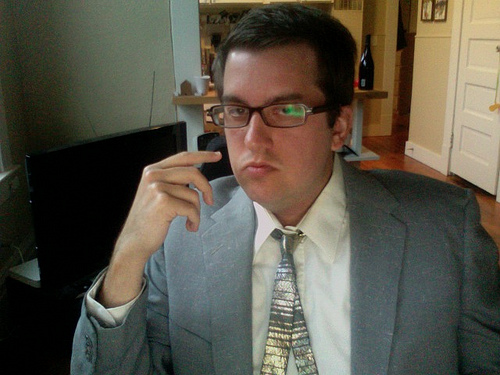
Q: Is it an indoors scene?
A: Yes, it is indoors.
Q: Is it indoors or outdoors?
A: It is indoors.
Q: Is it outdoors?
A: No, it is indoors.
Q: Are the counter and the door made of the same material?
A: Yes, both the counter and the door are made of wood.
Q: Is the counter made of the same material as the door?
A: Yes, both the counter and the door are made of wood.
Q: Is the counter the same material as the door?
A: Yes, both the counter and the door are made of wood.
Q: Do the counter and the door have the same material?
A: Yes, both the counter and the door are made of wood.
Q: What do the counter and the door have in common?
A: The material, both the counter and the door are wooden.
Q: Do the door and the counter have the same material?
A: Yes, both the door and the counter are made of wood.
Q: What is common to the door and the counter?
A: The material, both the door and the counter are wooden.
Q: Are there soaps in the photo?
A: No, there are no soaps.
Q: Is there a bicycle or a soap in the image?
A: No, there are no soaps or bicycles.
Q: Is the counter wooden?
A: Yes, the counter is wooden.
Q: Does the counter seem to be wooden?
A: Yes, the counter is wooden.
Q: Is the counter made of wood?
A: Yes, the counter is made of wood.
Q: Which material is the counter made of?
A: The counter is made of wood.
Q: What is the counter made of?
A: The counter is made of wood.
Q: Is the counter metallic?
A: No, the counter is wooden.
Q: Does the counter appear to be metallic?
A: No, the counter is wooden.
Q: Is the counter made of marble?
A: No, the counter is made of wood.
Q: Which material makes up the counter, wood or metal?
A: The counter is made of wood.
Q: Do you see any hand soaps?
A: No, there are no hand soaps.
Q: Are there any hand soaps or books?
A: No, there are no hand soaps or books.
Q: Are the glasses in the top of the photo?
A: Yes, the glasses are in the top of the image.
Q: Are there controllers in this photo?
A: No, there are no controllers.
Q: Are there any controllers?
A: No, there are no controllers.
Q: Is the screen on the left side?
A: Yes, the screen is on the left of the image.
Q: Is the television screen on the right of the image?
A: No, the screen is on the left of the image.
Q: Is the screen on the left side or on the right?
A: The screen is on the left of the image.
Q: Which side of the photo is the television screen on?
A: The screen is on the left of the image.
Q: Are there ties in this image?
A: Yes, there is a tie.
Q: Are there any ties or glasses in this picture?
A: Yes, there is a tie.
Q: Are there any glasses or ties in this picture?
A: Yes, there is a tie.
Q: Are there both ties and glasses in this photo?
A: Yes, there are both a tie and glasses.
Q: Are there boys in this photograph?
A: No, there are no boys.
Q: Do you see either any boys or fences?
A: No, there are no boys or fences.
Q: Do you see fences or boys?
A: No, there are no boys or fences.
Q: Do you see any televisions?
A: Yes, there is a television.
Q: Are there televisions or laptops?
A: Yes, there is a television.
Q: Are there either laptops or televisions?
A: Yes, there is a television.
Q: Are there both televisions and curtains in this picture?
A: No, there is a television but no curtains.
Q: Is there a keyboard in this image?
A: No, there are no keyboards.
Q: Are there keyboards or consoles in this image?
A: No, there are no keyboards or consoles.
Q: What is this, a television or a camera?
A: This is a television.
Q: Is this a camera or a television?
A: This is a television.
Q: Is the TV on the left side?
A: Yes, the TV is on the left of the image.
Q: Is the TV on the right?
A: No, the TV is on the left of the image.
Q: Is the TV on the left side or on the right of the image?
A: The TV is on the left of the image.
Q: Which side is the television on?
A: The television is on the left of the image.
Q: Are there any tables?
A: Yes, there is a table.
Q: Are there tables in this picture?
A: Yes, there is a table.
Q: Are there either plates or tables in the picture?
A: Yes, there is a table.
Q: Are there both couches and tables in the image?
A: No, there is a table but no couches.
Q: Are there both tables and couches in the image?
A: No, there is a table but no couches.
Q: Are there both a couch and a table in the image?
A: No, there is a table but no couches.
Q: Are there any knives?
A: No, there are no knives.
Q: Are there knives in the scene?
A: No, there are no knives.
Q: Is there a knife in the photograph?
A: No, there are no knives.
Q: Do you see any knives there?
A: No, there are no knives.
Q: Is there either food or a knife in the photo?
A: No, there are no knives or food.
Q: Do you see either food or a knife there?
A: No, there are no knives or food.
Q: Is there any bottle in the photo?
A: Yes, there is a bottle.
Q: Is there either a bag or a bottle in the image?
A: Yes, there is a bottle.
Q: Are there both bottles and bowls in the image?
A: No, there is a bottle but no bowls.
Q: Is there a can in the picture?
A: No, there are no cans.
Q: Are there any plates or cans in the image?
A: No, there are no cans or plates.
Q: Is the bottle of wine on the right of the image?
A: Yes, the bottle is on the right of the image.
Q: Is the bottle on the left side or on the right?
A: The bottle is on the right of the image.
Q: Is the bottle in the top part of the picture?
A: Yes, the bottle is in the top of the image.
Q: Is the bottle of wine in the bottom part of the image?
A: No, the bottle is in the top of the image.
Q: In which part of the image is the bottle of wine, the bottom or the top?
A: The bottle is in the top of the image.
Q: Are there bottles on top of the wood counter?
A: Yes, there is a bottle on top of the counter.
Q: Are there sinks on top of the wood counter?
A: No, there is a bottle on top of the counter.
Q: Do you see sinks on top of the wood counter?
A: No, there is a bottle on top of the counter.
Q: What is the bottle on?
A: The bottle is on the counter.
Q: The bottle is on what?
A: The bottle is on the counter.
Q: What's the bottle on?
A: The bottle is on the counter.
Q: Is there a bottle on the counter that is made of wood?
A: Yes, there is a bottle on the counter.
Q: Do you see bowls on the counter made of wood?
A: No, there is a bottle on the counter.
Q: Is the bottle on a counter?
A: Yes, the bottle is on a counter.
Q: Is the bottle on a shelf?
A: No, the bottle is on a counter.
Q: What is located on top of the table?
A: The bottle is on top of the table.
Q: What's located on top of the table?
A: The bottle is on top of the table.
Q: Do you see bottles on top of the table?
A: Yes, there is a bottle on top of the table.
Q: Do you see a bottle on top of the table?
A: Yes, there is a bottle on top of the table.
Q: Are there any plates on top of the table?
A: No, there is a bottle on top of the table.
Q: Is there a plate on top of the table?
A: No, there is a bottle on top of the table.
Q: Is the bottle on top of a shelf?
A: No, the bottle is on top of the table.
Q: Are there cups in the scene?
A: Yes, there is a cup.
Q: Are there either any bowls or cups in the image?
A: Yes, there is a cup.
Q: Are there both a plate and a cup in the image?
A: No, there is a cup but no plates.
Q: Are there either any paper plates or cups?
A: Yes, there is a paper cup.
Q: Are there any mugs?
A: No, there are no mugs.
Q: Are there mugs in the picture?
A: No, there are no mugs.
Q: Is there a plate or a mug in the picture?
A: No, there are no mugs or plates.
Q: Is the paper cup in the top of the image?
A: Yes, the cup is in the top of the image.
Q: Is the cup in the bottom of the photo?
A: No, the cup is in the top of the image.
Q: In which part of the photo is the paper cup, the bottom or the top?
A: The cup is in the top of the image.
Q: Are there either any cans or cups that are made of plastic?
A: No, there is a cup but it is made of paper.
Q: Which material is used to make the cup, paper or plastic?
A: The cup is made of paper.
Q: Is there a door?
A: Yes, there is a door.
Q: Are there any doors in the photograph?
A: Yes, there is a door.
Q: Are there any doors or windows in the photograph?
A: Yes, there is a door.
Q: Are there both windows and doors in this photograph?
A: No, there is a door but no windows.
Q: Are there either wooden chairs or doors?
A: Yes, there is a wood door.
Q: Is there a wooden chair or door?
A: Yes, there is a wood door.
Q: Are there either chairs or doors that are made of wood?
A: Yes, the door is made of wood.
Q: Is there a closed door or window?
A: Yes, there is a closed door.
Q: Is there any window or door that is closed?
A: Yes, the door is closed.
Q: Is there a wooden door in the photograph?
A: Yes, there is a wood door.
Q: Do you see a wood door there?
A: Yes, there is a wood door.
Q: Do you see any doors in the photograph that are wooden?
A: Yes, there is a door that is wooden.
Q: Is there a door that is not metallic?
A: Yes, there is a wooden door.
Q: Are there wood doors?
A: Yes, there is a door that is made of wood.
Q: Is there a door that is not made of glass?
A: Yes, there is a door that is made of wood.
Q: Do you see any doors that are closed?
A: Yes, there is a closed door.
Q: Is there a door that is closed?
A: Yes, there is a door that is closed.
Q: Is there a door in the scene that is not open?
A: Yes, there is an closed door.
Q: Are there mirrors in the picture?
A: No, there are no mirrors.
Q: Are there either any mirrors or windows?
A: No, there are no mirrors or windows.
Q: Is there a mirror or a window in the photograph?
A: No, there are no mirrors or windows.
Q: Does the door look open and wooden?
A: No, the door is wooden but closed.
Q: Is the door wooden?
A: Yes, the door is wooden.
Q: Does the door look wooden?
A: Yes, the door is wooden.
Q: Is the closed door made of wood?
A: Yes, the door is made of wood.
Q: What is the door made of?
A: The door is made of wood.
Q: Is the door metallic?
A: No, the door is wooden.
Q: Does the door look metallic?
A: No, the door is wooden.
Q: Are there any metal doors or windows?
A: No, there is a door but it is wooden.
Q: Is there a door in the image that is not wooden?
A: No, there is a door but it is wooden.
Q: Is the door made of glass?
A: No, the door is made of wood.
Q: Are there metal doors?
A: No, there is a door but it is made of wood.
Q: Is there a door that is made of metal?
A: No, there is a door but it is made of wood.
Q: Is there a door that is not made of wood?
A: No, there is a door but it is made of wood.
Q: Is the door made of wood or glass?
A: The door is made of wood.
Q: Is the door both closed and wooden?
A: Yes, the door is closed and wooden.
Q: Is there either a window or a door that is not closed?
A: No, there is a door but it is closed.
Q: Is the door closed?
A: Yes, the door is closed.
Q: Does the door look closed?
A: Yes, the door is closed.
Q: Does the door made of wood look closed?
A: Yes, the door is closed.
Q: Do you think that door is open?
A: No, the door is closed.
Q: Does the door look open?
A: No, the door is closed.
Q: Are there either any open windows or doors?
A: No, there is a door but it is closed.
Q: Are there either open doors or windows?
A: No, there is a door but it is closed.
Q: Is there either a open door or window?
A: No, there is a door but it is closed.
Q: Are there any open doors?
A: No, there is a door but it is closed.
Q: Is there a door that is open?
A: No, there is a door but it is closed.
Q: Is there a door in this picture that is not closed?
A: No, there is a door but it is closed.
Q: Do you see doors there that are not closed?
A: No, there is a door but it is closed.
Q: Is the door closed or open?
A: The door is closed.